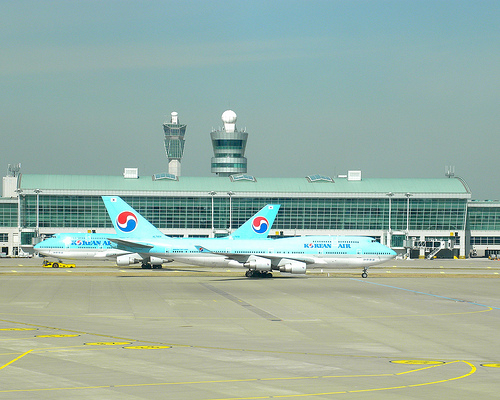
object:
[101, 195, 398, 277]
airplane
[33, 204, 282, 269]
airplane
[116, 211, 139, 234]
logo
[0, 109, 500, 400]
airport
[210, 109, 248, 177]
control tower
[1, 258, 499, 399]
tarmac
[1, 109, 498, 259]
terminal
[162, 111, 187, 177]
control tower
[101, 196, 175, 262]
tail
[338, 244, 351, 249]
word air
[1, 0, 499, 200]
sky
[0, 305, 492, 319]
line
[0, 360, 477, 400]
line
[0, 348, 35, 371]
line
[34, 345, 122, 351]
line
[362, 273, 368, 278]
tire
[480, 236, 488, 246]
window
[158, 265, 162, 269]
wheel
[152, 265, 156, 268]
wheel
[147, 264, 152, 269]
wheel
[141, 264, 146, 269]
wheel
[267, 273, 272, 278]
wheel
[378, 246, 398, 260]
nose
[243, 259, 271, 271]
engine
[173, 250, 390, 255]
window row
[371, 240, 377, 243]
windshield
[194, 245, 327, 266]
wing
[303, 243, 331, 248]
word korean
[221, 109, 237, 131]
object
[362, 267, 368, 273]
landing gear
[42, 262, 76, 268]
object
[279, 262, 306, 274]
engine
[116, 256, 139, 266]
engine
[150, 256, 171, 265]
engine